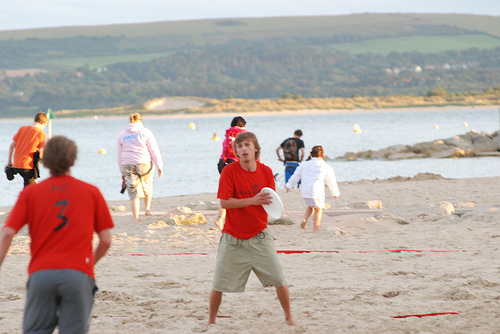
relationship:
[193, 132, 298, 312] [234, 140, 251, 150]
man has eyes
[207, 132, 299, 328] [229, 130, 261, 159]
man has hair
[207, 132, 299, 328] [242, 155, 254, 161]
man has chin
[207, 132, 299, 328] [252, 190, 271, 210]
man has hand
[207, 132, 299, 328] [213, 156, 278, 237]
man wears shirt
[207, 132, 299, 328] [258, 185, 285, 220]
man holds frisbee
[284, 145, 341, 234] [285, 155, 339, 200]
girl wears white jacket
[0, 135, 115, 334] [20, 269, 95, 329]
man wearing shorts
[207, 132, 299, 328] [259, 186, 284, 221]
man holding frisbee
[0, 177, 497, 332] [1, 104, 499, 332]
sand at beach